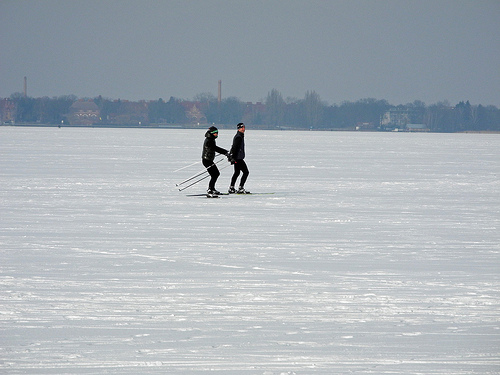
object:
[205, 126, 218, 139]
head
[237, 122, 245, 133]
head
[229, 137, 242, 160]
arm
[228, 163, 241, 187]
leg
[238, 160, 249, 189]
leg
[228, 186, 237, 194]
foot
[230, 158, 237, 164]
hand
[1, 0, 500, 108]
sky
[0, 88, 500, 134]
trees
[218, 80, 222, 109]
smokestack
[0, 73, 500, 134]
horizon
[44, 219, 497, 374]
snow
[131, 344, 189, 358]
foot print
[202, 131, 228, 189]
clothing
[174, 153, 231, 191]
ski pole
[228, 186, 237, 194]
boot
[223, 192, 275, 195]
ski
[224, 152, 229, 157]
hand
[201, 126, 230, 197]
girl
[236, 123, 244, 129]
hat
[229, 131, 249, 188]
clothing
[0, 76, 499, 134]
houses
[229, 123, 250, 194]
man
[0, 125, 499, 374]
ice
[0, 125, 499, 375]
floor